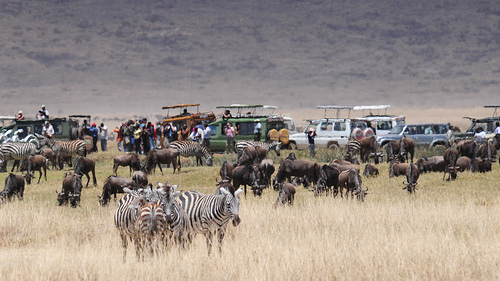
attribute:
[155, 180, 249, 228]
zebra — standing, black, white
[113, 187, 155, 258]
zebra — standing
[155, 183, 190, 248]
zebra — standing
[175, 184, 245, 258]
zebra — standing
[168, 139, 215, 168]
zebra — standing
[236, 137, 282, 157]
zebra — standing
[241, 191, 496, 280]
grass — overgrown, high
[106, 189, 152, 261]
zebra — white, black, standing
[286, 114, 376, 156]
vehicle — white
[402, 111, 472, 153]
vehicle — silver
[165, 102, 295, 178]
truck — green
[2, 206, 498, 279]
field — grass, grassy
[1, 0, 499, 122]
plains — empty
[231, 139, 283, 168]
zebra — standing, black, white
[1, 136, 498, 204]
cattle — eating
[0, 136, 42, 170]
zebra — standing, black, white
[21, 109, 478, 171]
vehicles — parked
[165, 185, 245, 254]
zebra — white, brown, standing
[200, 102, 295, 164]
safari vehicle — green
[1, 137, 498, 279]
grass — long, yellow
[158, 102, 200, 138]
car — orange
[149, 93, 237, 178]
vehicle — orange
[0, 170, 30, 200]
animal — brown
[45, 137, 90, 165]
zebra — brown, white, striped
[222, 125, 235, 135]
shirt — pink